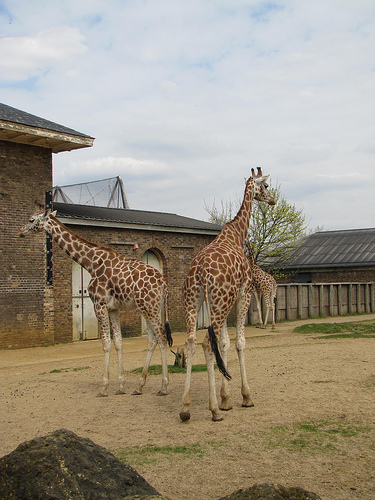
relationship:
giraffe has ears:
[19, 203, 177, 397] [43, 205, 58, 221]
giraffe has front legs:
[19, 203, 177, 397] [94, 310, 128, 397]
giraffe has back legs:
[19, 203, 177, 397] [130, 312, 170, 396]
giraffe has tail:
[19, 203, 177, 397] [162, 286, 176, 348]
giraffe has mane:
[19, 203, 177, 397] [47, 212, 118, 257]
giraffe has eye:
[19, 203, 177, 397] [29, 216, 37, 225]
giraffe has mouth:
[19, 203, 177, 397] [19, 232, 25, 239]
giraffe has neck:
[19, 203, 177, 397] [52, 220, 95, 273]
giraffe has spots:
[19, 203, 177, 397] [103, 278, 144, 302]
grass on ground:
[295, 321, 373, 343] [0, 311, 373, 499]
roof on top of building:
[55, 204, 220, 235] [53, 208, 240, 342]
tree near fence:
[214, 180, 308, 288] [237, 278, 373, 329]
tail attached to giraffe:
[202, 273, 234, 384] [179, 168, 277, 425]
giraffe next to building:
[241, 240, 278, 331] [53, 208, 240, 342]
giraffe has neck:
[241, 240, 278, 331] [246, 247, 258, 266]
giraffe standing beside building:
[241, 240, 278, 331] [53, 208, 240, 342]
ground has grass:
[0, 311, 373, 499] [282, 414, 374, 454]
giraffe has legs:
[179, 168, 277, 425] [168, 313, 251, 424]